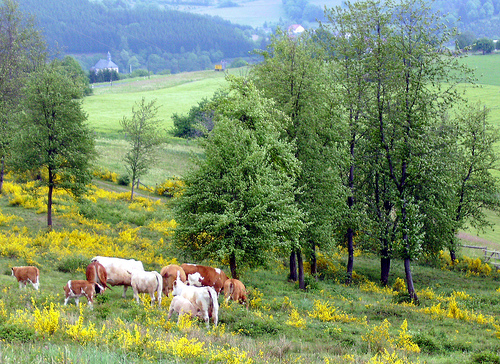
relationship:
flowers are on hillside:
[308, 277, 500, 364] [4, 126, 499, 362]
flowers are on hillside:
[404, 295, 494, 325] [4, 126, 499, 362]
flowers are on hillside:
[0, 295, 106, 338] [4, 126, 499, 362]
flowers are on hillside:
[0, 172, 186, 268] [4, 126, 499, 362]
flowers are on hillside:
[0, 206, 179, 268] [4, 126, 499, 362]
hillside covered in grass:
[56, 54, 497, 235] [0, 52, 500, 364]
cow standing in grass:
[11, 256, 250, 331] [44, 274, 284, 362]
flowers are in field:
[0, 294, 264, 364] [65, 47, 498, 202]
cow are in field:
[11, 256, 250, 331] [264, 268, 499, 356]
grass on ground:
[420, 329, 471, 353] [17, 283, 490, 361]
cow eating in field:
[181, 256, 249, 301] [38, 39, 489, 361]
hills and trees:
[24, 12, 287, 113] [1, 0, 285, 85]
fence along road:
[453, 237, 498, 259] [85, 170, 498, 257]